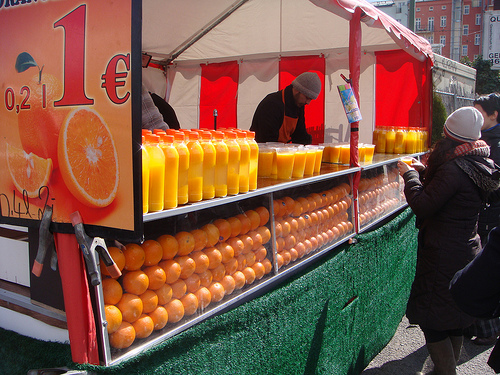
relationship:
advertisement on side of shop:
[3, 14, 139, 227] [1, 0, 484, 370]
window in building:
[441, 17, 448, 30] [392, 3, 495, 68]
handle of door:
[206, 108, 230, 137] [7, 117, 157, 356]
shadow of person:
[345, 345, 430, 373] [396, 104, 481, 373]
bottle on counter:
[141, 127, 258, 214] [133, 147, 386, 236]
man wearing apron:
[249, 72, 323, 144] [276, 87, 300, 142]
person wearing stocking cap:
[397, 105, 500, 375] [443, 104, 483, 141]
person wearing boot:
[397, 105, 500, 375] [423, 336, 459, 374]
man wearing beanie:
[245, 69, 322, 146] [294, 71, 318, 95]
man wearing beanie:
[249, 72, 323, 144] [291, 71, 322, 100]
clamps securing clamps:
[19, 199, 146, 356] [30, 207, 123, 367]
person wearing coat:
[397, 105, 500, 375] [396, 141, 498, 350]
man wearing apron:
[249, 72, 323, 144] [269, 83, 303, 138]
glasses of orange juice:
[275, 151, 293, 182] [275, 152, 320, 180]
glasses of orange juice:
[294, 145, 306, 177] [376, 132, 428, 152]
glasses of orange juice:
[305, 146, 324, 174] [327, 144, 373, 163]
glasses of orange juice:
[363, 140, 375, 162] [140, 141, 200, 212]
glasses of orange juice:
[329, 142, 349, 163] [202, 142, 257, 198]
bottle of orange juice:
[144, 135, 164, 212] [137, 124, 258, 211]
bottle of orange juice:
[187, 131, 204, 201] [137, 124, 258, 211]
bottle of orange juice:
[212, 132, 226, 198] [137, 124, 258, 211]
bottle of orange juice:
[237, 130, 250, 192] [137, 124, 258, 211]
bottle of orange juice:
[247, 130, 258, 191] [137, 124, 258, 211]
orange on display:
[120, 241, 148, 271] [77, 198, 278, 369]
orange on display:
[154, 231, 181, 261] [77, 198, 278, 369]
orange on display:
[170, 227, 197, 259] [77, 198, 278, 369]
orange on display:
[211, 216, 234, 244] [77, 198, 278, 369]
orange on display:
[101, 302, 126, 334] [77, 198, 278, 369]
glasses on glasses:
[259, 139, 321, 192] [254, 142, 325, 180]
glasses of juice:
[259, 139, 321, 192] [256, 143, 326, 190]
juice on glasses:
[256, 143, 326, 190] [254, 142, 325, 180]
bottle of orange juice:
[145, 121, 263, 217] [159, 126, 280, 193]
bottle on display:
[145, 121, 263, 217] [133, 129, 324, 214]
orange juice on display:
[159, 126, 280, 193] [133, 129, 324, 214]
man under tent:
[249, 72, 323, 144] [198, 0, 457, 93]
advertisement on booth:
[0, 0, 150, 245] [26, 2, 434, 367]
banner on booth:
[2, 0, 143, 240] [26, 2, 434, 367]